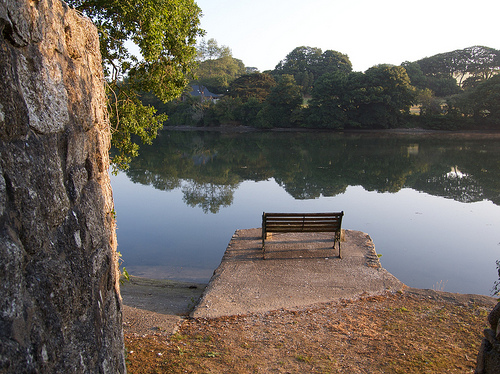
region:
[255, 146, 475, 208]
refeltion is in the water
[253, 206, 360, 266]
the bench is wooden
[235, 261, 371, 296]
the surface is concrete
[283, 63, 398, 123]
trees are in the background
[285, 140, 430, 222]
the water is calm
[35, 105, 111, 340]
the bark is grey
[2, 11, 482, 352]
the photo is clear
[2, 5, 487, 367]
the scenery is outside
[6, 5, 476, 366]
the scene was taken during the day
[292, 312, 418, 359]
small patches of grass on the ground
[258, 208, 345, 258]
Wooden bench on cement area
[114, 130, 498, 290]
Large lake in front of bench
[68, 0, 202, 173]
Tree next to bench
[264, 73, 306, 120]
Big tree along lake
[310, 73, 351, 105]
Big tree along lake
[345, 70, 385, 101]
Big tree along lake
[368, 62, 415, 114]
Big tree along lake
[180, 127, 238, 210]
Reflection of tree on lake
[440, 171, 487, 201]
Reflection of tree on lake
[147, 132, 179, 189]
Reflection of tree on lake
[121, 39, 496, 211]
The trees are reflected in the water.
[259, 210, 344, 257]
Bench with one vertical slat in middle.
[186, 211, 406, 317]
Bench sitting on cement platform.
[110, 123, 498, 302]
Water has no ripples or visible movement.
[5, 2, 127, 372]
Stone wall with light color on right corner.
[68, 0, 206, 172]
Tree overhanging water beyond stone wall.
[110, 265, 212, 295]
Water meets cement surface.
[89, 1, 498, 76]
Sky above trees is bright with light.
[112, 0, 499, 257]
Bench overlooking water and trees.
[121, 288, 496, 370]
Almost bare ground meets cement.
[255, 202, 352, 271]
Small bench on pavement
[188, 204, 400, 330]
Small slab of pavement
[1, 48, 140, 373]
Part of a brick wall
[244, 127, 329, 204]
Reflection of Trees in water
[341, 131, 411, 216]
Reflection of Trees in water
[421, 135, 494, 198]
Reflection of Trees in water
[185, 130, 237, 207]
Reflection of Trees in water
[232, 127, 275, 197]
Reflection of Trees in water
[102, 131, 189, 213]
Reflection of Trees in water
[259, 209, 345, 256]
Wooden bench facing a pond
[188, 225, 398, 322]
Concrete outreach into a pond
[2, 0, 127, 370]
Stone wall in the foreground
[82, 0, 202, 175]
Green leaves on a nearby tree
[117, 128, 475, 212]
Reflection of distant trees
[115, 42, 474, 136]
Trees on the far shore of the lake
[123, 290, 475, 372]
Grass and dirt on the shore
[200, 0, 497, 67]
Clear, bright blue sky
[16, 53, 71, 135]
Light colored stone in a wall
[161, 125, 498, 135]
Dirt beach on the opposite shore